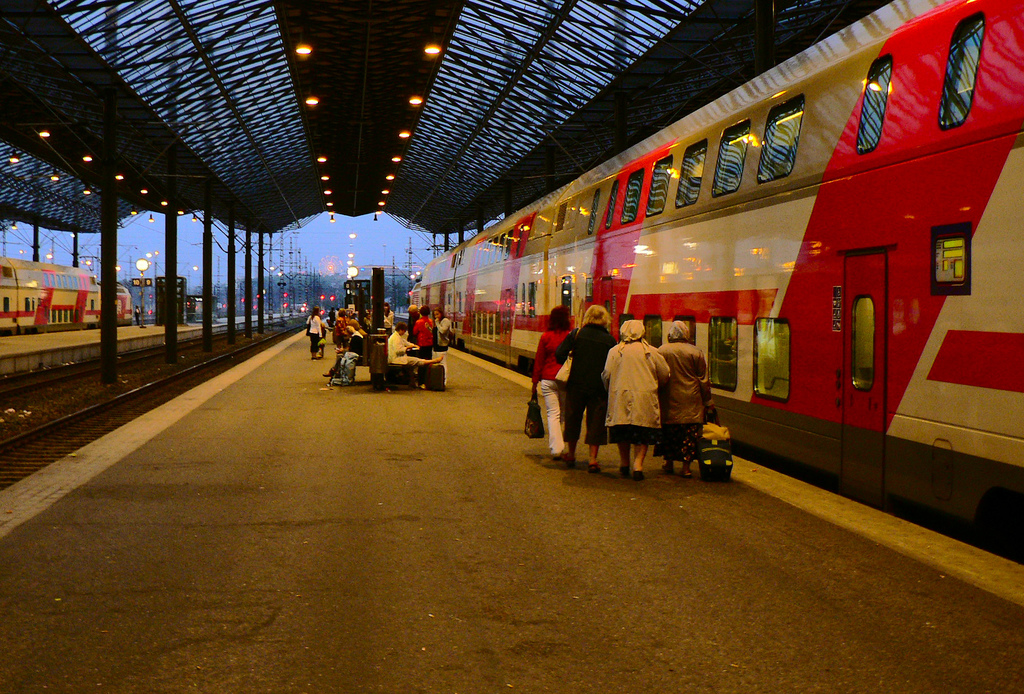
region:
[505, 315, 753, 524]
four women getting on the train.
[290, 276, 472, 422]
people sitting on the bench.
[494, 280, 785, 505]
Four old women getting on the train.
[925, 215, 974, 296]
Operating system on the side of train.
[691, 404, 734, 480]
Black luggage on the side of the sidewalk.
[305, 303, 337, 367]
Person standing in a white and black shirt.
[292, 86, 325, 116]
Light hanging from the ceiling.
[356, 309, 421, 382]
Benches in the middle filled with people.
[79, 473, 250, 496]
Large stain on the top of the sidewalk.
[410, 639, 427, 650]
White piece of paper on the ground.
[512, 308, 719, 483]
the ladies walking beside the train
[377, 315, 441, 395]
the person sitting waiting for the train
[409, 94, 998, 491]
the large red and white train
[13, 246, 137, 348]
the other train at the station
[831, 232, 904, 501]
the door to the train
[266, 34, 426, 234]
the lights above the station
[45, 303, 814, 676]
the concrete waiting platform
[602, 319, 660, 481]
the short lady in the skirt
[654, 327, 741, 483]
the lady pulling her luggage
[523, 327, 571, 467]
the lady in red and white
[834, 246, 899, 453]
red door on the train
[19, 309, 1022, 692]
platform at the station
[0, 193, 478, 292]
blue colored sky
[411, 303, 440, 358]
person with a red shirt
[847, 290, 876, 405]
window on a red door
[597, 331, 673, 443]
light colored jacket on an old woman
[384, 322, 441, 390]
person with a white shirt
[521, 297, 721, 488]
four women walk together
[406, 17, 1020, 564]
the train on the right is red gold and white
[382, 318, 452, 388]
a woman props her leg up on her bag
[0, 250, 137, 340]
the train on the left is red white and gold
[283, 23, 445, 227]
lighting for the loading platform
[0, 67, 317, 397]
power lines for electric locomotives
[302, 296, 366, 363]
people read the train board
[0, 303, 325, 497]
these tracks are empty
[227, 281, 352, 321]
red track signals in the distance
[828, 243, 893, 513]
doorway on the closest train car